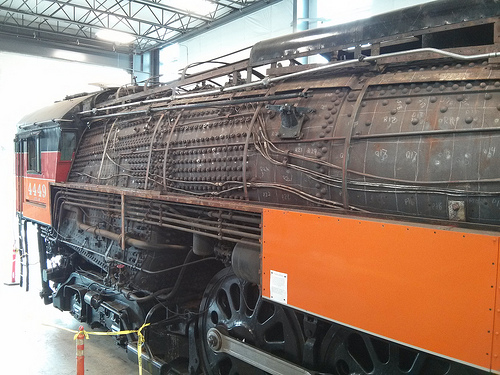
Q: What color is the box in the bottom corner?
A: Orange.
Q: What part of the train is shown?
A: Engine.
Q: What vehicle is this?
A: Train.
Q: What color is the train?
A: Orange and black.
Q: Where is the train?
A: Museum.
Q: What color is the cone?
A: Orange.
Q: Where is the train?
A: Inside a building.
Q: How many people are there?
A: None.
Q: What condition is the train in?
A: Old.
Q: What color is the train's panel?
A: Orange.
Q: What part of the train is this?
A: Locomotive.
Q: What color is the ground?
A: Grey.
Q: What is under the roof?
A: Locomotive.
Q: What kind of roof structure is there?
A: Metal.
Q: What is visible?
A: Locomotive.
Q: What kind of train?
A: Rusty train.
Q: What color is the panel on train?
A: Orange.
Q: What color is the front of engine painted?
A: Red and orange.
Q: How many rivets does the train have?
A: Many rivets.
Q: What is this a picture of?
A: A train.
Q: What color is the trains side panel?
A: Orange.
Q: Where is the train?
A: In the station.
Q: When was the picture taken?
A: During the day.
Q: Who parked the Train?
A: The conductor.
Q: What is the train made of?
A: Metal.